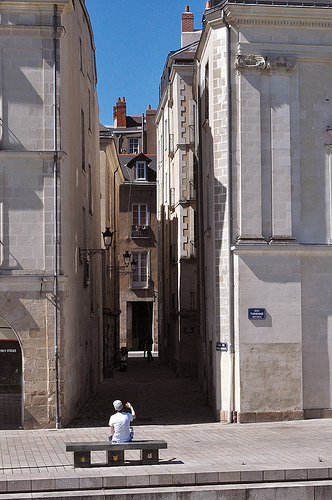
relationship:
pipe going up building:
[51, 3, 61, 427] [1, 0, 122, 427]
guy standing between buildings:
[108, 400, 136, 443] [1, 1, 328, 429]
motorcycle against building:
[117, 342, 130, 372] [0, 0, 104, 426]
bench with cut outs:
[63, 440, 167, 466] [77, 450, 153, 463]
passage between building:
[80, 227, 209, 423] [164, 27, 329, 422]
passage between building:
[80, 227, 209, 423] [4, 4, 113, 440]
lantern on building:
[99, 226, 115, 249] [197, 9, 325, 421]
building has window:
[101, 93, 167, 369] [132, 252, 148, 282]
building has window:
[101, 93, 167, 369] [132, 204, 145, 225]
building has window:
[101, 93, 167, 369] [137, 162, 143, 177]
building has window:
[101, 93, 167, 369] [128, 137, 138, 153]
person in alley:
[142, 328, 154, 361] [68, 351, 214, 435]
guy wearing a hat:
[108, 398, 137, 441] [111, 399, 123, 409]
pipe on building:
[51, 3, 61, 427] [4, 4, 113, 440]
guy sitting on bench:
[108, 400, 136, 443] [61, 435, 168, 466]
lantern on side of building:
[102, 227, 115, 249] [0, 0, 104, 426]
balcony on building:
[129, 247, 150, 291] [87, 105, 200, 380]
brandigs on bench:
[69, 449, 161, 468] [62, 438, 169, 464]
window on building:
[136, 159, 146, 179] [101, 93, 167, 369]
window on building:
[129, 138, 139, 153] [101, 93, 167, 369]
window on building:
[132, 203, 150, 227] [101, 93, 167, 369]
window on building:
[130, 250, 148, 289] [101, 93, 167, 369]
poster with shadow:
[244, 303, 278, 324] [256, 315, 274, 327]